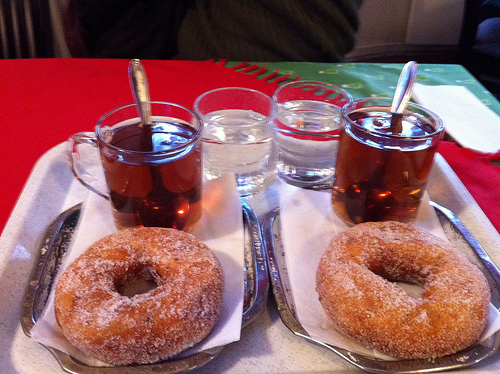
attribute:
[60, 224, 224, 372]
doughnut — cooked, sugar covered, brown, iced, sugared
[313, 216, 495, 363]
doughnut — cooked, sugar covered, brown, iced, sugared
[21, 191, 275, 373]
plate — silver, metalic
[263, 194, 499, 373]
plate — silver, metalic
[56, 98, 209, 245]
glass — clear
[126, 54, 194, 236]
spoon — silver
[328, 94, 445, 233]
glass — clear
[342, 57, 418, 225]
spoon — silver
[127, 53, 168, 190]
handle — silver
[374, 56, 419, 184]
handle — silver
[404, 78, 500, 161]
napkin — white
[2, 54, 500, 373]
table — red, green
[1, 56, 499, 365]
table cloth — red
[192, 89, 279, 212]
glass — clear, small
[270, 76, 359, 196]
glass — clear, small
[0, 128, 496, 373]
tray — gray, plastic, silver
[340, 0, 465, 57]
wall — white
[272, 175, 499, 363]
napkin — white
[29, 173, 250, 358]
napkin — white